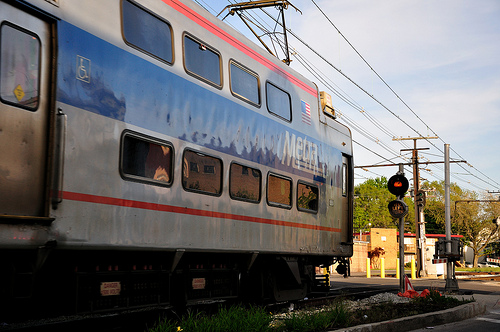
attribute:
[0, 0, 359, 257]
train — silver, red, blue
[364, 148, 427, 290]
light — illuminated, red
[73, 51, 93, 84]
sign — white, handicapped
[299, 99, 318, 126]
flag — american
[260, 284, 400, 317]
tracks — train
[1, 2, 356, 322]
train — silver, red, blue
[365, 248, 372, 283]
post — yellow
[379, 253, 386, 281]
post — yellow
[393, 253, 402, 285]
post — yellow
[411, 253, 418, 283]
post — yellow